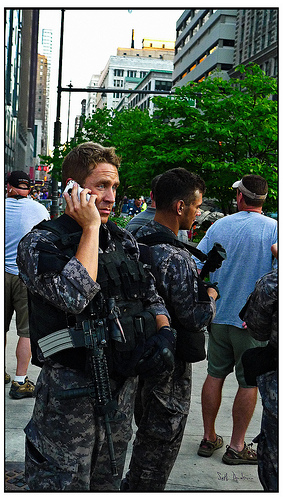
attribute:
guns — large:
[36, 254, 127, 471]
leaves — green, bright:
[70, 66, 274, 201]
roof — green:
[123, 69, 171, 79]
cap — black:
[3, 167, 31, 190]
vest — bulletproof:
[19, 216, 157, 378]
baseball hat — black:
[5, 168, 30, 193]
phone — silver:
[61, 181, 92, 209]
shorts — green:
[203, 312, 272, 389]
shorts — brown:
[4, 269, 34, 339]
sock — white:
[12, 373, 30, 383]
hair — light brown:
[60, 139, 121, 182]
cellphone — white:
[62, 179, 90, 212]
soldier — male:
[16, 138, 180, 490]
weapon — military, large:
[35, 286, 131, 476]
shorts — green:
[206, 319, 268, 387]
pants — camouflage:
[22, 351, 140, 489]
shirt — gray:
[187, 209, 276, 327]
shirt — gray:
[194, 211, 278, 330]